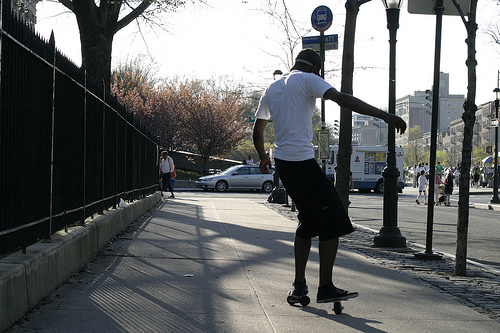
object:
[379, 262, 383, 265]
cobblestone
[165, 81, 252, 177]
tree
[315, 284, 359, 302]
shoes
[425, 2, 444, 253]
poles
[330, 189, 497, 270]
street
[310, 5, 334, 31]
sign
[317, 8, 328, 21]
bus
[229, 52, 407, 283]
man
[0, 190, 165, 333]
base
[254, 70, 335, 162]
shirt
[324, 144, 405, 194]
truck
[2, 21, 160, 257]
fence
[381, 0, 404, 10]
lamp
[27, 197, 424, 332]
sidewalk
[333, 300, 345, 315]
wheels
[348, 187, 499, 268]
road